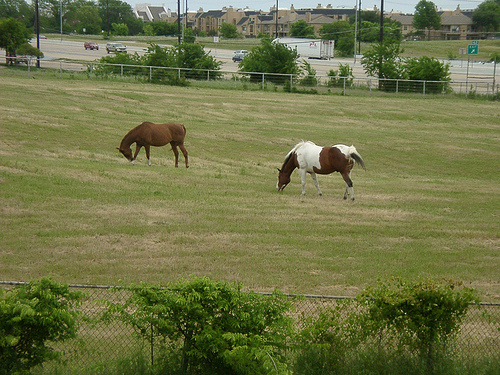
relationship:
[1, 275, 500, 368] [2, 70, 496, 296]
fences around grass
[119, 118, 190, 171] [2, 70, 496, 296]
brown horse eats grass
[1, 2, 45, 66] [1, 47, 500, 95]
tree near to far fence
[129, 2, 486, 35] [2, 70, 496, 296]
houses across from field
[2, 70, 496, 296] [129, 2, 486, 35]
grass across from houses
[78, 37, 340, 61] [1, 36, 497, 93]
traffic on street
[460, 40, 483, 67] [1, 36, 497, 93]
sign on street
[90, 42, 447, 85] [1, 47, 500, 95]
bushes next to far fence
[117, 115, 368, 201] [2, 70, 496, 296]
two horses on grass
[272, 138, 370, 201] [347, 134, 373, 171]
horse with white flipping h tail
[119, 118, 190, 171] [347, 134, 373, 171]
brown horse shows no tail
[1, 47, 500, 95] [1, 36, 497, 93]
far fence keeps them from street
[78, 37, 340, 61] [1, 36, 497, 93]
traffic in on a highway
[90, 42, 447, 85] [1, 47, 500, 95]
bushes grow along far fence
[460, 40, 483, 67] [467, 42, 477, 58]
sign says exit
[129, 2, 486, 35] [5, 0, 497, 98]
houses in background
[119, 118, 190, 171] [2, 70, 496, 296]
brown horse in pasture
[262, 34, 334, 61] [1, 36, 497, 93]
truck on street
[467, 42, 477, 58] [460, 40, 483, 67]
exit on a sign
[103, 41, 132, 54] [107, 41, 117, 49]
pickup beige with cap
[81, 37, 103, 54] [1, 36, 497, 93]
car on street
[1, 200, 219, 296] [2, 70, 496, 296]
brown sections of grass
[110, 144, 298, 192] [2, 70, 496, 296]
grazing on grass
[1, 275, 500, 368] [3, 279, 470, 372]
fences support growing plants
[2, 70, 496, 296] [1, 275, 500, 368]
grass enclosed by fences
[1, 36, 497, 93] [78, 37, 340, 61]
highway has traffic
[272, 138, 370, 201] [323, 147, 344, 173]
horse with white also has brown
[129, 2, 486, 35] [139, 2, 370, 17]
houses have dark roofs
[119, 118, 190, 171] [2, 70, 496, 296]
brown horse stands in grass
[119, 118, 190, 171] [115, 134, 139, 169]
brown horse has bent head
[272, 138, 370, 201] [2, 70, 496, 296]
horse with white stands in grass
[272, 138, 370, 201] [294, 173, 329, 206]
horse with white has white legs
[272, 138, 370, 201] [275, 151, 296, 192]
horse with white has a brown head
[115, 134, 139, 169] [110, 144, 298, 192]
head bent grazing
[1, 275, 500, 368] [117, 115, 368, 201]
fences around two horses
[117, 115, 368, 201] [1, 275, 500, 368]
two horses inside fences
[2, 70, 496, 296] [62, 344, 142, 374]
grass brown and green